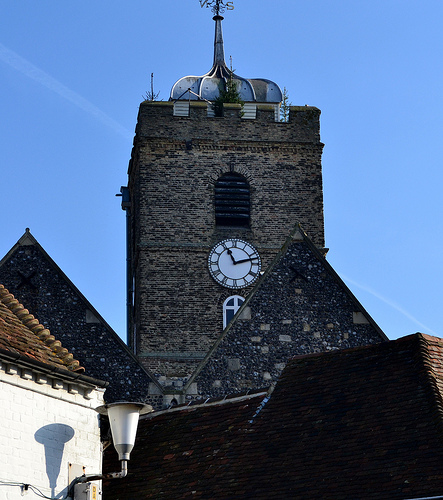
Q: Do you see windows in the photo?
A: Yes, there is a window.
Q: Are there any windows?
A: Yes, there is a window.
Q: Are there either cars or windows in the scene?
A: Yes, there is a window.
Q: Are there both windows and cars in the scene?
A: No, there is a window but no cars.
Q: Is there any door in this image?
A: No, there are no doors.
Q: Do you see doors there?
A: No, there are no doors.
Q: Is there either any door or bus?
A: No, there are no doors or buses.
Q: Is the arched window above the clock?
A: Yes, the window is above the clock.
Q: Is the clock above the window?
A: No, the window is above the clock.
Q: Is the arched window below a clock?
A: No, the window is above a clock.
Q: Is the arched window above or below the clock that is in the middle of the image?
A: The window is above the clock.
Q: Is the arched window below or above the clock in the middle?
A: The window is above the clock.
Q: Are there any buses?
A: No, there are no buses.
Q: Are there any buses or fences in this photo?
A: No, there are no buses or fences.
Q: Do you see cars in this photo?
A: No, there are no cars.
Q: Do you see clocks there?
A: Yes, there is a clock.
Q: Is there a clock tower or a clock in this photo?
A: Yes, there is a clock.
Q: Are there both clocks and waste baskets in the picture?
A: No, there is a clock but no waste baskets.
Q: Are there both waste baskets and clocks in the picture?
A: No, there is a clock but no waste baskets.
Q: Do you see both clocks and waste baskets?
A: No, there is a clock but no waste baskets.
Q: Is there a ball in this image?
A: No, there are no balls.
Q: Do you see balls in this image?
A: No, there are no balls.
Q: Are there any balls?
A: No, there are no balls.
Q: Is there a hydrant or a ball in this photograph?
A: No, there are no balls or fire hydrants.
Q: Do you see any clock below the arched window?
A: Yes, there is a clock below the window.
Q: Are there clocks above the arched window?
A: No, the clock is below the window.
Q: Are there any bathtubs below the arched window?
A: No, there is a clock below the window.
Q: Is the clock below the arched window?
A: Yes, the clock is below the window.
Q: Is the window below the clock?
A: No, the clock is below the window.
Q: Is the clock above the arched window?
A: No, the clock is below the window.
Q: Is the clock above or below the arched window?
A: The clock is below the window.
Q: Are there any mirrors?
A: No, there are no mirrors.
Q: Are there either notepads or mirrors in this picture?
A: No, there are no mirrors or notepads.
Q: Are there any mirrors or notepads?
A: No, there are no mirrors or notepads.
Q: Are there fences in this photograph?
A: No, there are no fences.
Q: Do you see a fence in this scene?
A: No, there are no fences.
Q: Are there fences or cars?
A: No, there are no fences or cars.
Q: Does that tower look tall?
A: Yes, the tower is tall.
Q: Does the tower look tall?
A: Yes, the tower is tall.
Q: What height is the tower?
A: The tower is tall.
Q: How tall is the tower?
A: The tower is tall.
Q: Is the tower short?
A: No, the tower is tall.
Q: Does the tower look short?
A: No, the tower is tall.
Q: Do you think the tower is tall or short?
A: The tower is tall.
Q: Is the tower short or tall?
A: The tower is tall.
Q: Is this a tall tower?
A: Yes, this is a tall tower.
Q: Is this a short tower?
A: No, this is a tall tower.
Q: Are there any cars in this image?
A: No, there are no cars.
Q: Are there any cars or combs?
A: No, there are no cars or combs.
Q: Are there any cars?
A: No, there are no cars.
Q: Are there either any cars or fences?
A: No, there are no cars or fences.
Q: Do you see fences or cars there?
A: No, there are no cars or fences.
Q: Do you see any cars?
A: No, there are no cars.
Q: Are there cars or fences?
A: No, there are no cars or fences.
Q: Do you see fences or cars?
A: No, there are no cars or fences.